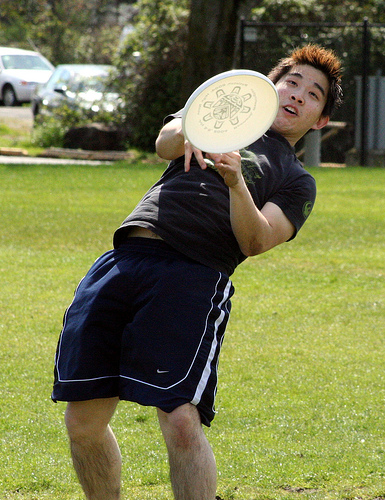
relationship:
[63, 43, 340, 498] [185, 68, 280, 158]
guy catching frisbee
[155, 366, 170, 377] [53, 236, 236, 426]
logo on shorts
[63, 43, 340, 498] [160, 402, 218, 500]
guy has leg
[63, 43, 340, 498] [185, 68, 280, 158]
guy has frisbee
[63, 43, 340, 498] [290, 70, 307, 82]
guy has eyebrow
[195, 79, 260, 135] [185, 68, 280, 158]
design on frisbee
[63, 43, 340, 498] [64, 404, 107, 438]
guy has knee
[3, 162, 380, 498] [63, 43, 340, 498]
grass behind guy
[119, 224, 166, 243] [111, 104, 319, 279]
stomach under tshirt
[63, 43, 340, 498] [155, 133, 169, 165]
guy has elbow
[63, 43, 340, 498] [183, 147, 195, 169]
guy has finger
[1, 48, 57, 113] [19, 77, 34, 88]
vehicle has light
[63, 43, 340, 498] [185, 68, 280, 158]
guy holding frisbee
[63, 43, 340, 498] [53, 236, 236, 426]
guy wearing shorts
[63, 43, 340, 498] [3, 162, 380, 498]
guy on grass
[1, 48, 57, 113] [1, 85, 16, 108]
vehicle has tire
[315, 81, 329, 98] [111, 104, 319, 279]
man wearing tshirt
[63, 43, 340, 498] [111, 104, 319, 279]
guy wearing tshirt